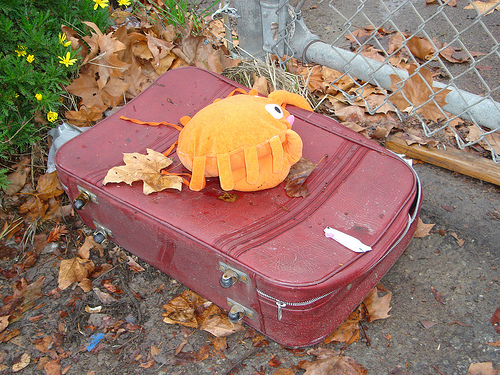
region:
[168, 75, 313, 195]
an orange stuffed spider on a suitcase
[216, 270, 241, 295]
the wheels on a suit case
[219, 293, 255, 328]
the wheels on a suit case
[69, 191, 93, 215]
the wheels on a suit case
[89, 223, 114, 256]
the wheels on a suit case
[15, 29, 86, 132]
several little yellow wild flowers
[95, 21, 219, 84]
dried leaves on the ground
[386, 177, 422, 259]
a zipper of a suite case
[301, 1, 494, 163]
the bottom of a chain length fence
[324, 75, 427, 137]
dried leaves on ground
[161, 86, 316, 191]
an orange stuffed toy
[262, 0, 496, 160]
a metal chain link fence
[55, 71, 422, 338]
a ragged old red suitcase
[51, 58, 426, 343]
an orange plush toy on a red suitcase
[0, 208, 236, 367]
a pile of dirty leaves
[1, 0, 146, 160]
a pile of flowers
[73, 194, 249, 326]
wheels on a red suitcase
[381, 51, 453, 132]
a leaf stuck in a chain link fence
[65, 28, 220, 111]
a pile of orange leaves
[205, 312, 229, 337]
leaf on the ground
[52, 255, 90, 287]
leaf on the ground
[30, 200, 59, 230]
leaf on the ground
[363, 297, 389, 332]
leaf on the ground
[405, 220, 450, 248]
leaf on the ground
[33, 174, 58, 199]
leaf on the ground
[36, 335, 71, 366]
leaf on the ground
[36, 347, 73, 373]
leaf on the ground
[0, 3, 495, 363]
a suitcase on the ground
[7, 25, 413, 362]
fallen autumn leaves on the ground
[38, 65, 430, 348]
a red suitcase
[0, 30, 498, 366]
the asphalt ground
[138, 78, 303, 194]
an orange crab stuffed animal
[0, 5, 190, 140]
plant with yellow flowers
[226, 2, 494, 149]
the bottom of a chainlink fence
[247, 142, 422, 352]
the suitcase is unzipped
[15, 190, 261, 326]
the suitcase has wheels on the bottom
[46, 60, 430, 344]
suitcase is dirty